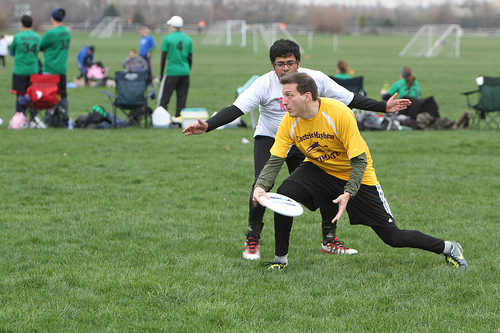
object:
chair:
[456, 76, 498, 131]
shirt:
[159, 29, 191, 79]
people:
[6, 7, 198, 123]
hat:
[163, 14, 185, 28]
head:
[168, 15, 183, 32]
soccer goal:
[395, 23, 464, 60]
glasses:
[273, 60, 298, 70]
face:
[272, 56, 299, 77]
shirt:
[6, 27, 42, 77]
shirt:
[39, 25, 73, 72]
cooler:
[177, 105, 209, 132]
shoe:
[441, 239, 469, 272]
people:
[182, 37, 472, 275]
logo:
[302, 140, 343, 164]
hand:
[248, 185, 267, 206]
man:
[251, 70, 472, 272]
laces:
[242, 235, 263, 254]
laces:
[327, 239, 346, 255]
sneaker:
[242, 234, 261, 261]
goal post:
[394, 20, 433, 57]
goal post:
[456, 24, 463, 60]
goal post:
[427, 24, 435, 57]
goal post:
[224, 20, 234, 46]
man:
[154, 15, 196, 123]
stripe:
[320, 110, 341, 141]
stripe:
[289, 118, 299, 141]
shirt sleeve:
[347, 93, 387, 112]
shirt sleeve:
[202, 104, 246, 134]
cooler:
[149, 106, 172, 127]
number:
[173, 39, 185, 55]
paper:
[240, 136, 252, 145]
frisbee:
[254, 188, 303, 218]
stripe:
[374, 183, 394, 225]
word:
[294, 130, 336, 143]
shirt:
[269, 93, 379, 185]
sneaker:
[318, 237, 358, 255]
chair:
[105, 69, 149, 130]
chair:
[17, 69, 66, 129]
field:
[0, 31, 499, 327]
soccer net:
[395, 23, 463, 60]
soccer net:
[198, 18, 246, 48]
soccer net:
[88, 14, 125, 39]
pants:
[272, 160, 450, 255]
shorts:
[276, 158, 396, 224]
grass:
[0, 30, 500, 329]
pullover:
[268, 95, 379, 187]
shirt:
[227, 66, 357, 141]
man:
[40, 7, 73, 120]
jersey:
[38, 24, 72, 76]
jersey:
[6, 29, 44, 77]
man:
[5, 14, 44, 127]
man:
[178, 39, 411, 260]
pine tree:
[130, 7, 146, 30]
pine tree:
[101, 1, 121, 26]